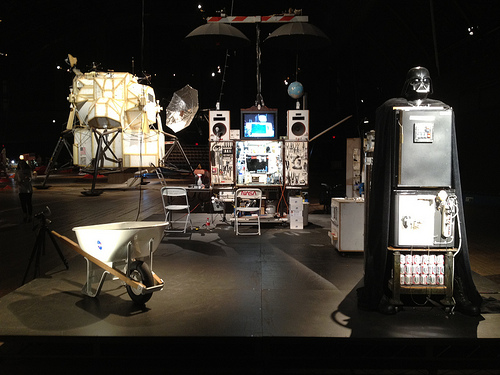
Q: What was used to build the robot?
A: A mask and boxes.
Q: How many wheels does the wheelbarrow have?
A: One.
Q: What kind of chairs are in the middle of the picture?
A: Folding chairs,.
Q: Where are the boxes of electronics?
A: On the table in the center of the image.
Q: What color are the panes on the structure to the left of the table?
A: White.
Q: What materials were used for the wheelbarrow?
A: Metal and wood.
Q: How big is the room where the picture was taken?
A: Very big.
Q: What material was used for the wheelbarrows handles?
A: Wood.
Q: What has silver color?
A: Robots.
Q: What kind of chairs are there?
A: Folding chairs.